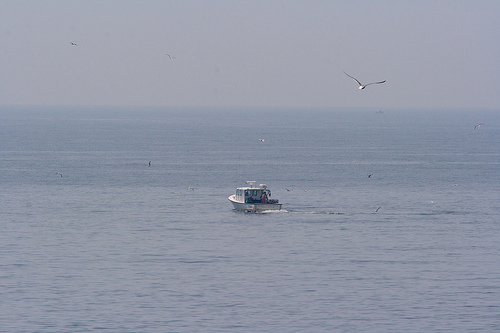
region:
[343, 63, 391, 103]
Long wings of a bird.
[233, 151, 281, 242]
a boat on the water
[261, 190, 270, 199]
Some people on a boat.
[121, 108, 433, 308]
a large body of blue water.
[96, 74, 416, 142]
A hazy horizon.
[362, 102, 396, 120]
A boat in the distance.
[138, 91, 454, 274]
Many birds fly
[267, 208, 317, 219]
waves of water from the motor of the vessel.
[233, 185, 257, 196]
The cabin of the ship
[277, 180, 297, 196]
A bird flying near the ship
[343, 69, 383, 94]
a seagull flying in the sky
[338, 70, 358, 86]
the wing of a seagull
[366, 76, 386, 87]
the wing of a seagull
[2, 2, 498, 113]
the pale blue sky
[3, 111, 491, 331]
the pale blue sea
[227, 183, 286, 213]
a small white boat boating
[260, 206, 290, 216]
the wake from a boat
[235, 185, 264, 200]
the cabin of a boat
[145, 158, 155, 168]
a black spot in the ocean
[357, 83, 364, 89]
the body of a seagull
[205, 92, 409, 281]
A boat heading out to sea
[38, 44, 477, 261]
Perfect fishing weather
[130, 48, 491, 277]
Seagulls flying high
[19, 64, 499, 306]
Beautiful blue water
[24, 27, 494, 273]
Beautiful blue skies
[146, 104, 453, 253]
People fishing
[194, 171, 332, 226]
People checking trot lines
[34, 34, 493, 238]
Seagulls looking for their prey below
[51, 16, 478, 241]
A swarm of birds above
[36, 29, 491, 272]
Heading out to make that money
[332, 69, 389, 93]
bird flying overhead of boat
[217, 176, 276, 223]
boat with people on it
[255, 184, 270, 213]
person wearing red pants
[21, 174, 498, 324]
the water is calm and blue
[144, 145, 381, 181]
buoys in the water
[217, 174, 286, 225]
boat is alone in the water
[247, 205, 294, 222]
white wave from the motor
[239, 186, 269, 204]
windows in the cabin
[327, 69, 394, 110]
the bird is white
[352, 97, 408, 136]
a boat on the horizon